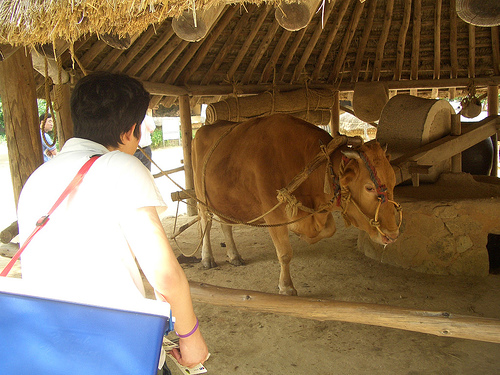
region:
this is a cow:
[203, 123, 383, 250]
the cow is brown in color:
[213, 107, 385, 264]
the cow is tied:
[297, 160, 347, 227]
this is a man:
[20, 71, 170, 281]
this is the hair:
[81, 79, 131, 123]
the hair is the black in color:
[80, 78, 129, 115]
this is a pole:
[363, 297, 411, 337]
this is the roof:
[317, 28, 368, 65]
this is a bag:
[24, 292, 152, 371]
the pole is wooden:
[333, 303, 380, 333]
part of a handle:
[179, 328, 205, 360]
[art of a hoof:
[282, 278, 300, 302]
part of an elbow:
[131, 226, 216, 319]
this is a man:
[46, 89, 192, 374]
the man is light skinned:
[133, 218, 173, 268]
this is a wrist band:
[181, 315, 198, 339]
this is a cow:
[235, 113, 405, 250]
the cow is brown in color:
[242, 134, 277, 184]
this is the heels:
[276, 283, 308, 303]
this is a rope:
[313, 170, 360, 213]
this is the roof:
[373, 9, 448, 67]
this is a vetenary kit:
[36, 315, 112, 374]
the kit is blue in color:
[46, 313, 103, 360]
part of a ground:
[267, 339, 287, 359]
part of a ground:
[318, 280, 351, 303]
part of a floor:
[361, 257, 402, 299]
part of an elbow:
[152, 258, 174, 303]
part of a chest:
[291, 203, 344, 283]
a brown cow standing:
[191, 120, 401, 295]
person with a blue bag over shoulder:
[5, 75, 208, 372]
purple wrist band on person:
[176, 317, 196, 335]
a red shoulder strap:
[1, 151, 97, 281]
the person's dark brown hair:
[67, 70, 148, 145]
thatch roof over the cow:
[2, 0, 499, 90]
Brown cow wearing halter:
[186, 119, 407, 298]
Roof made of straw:
[2, 2, 496, 41]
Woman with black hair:
[5, 64, 213, 374]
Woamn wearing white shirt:
[0, 74, 212, 372]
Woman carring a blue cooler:
[0, 65, 215, 374]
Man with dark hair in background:
[30, 106, 52, 151]